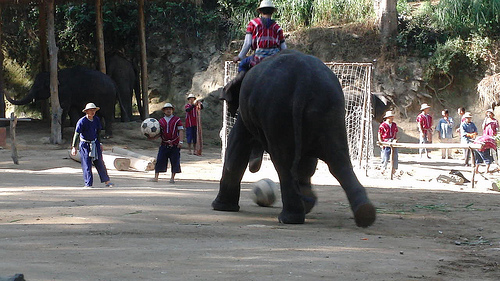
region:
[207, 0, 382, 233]
a man riding an elephant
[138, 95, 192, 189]
a man holding a large soccer ball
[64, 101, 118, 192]
a man wearing blue and brimmed hat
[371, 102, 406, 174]
a man wearing a red shirt and a hat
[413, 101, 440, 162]
a man wearing a red shirt and a hat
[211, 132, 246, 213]
a front leg of an elephant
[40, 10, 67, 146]
the trunk of a tree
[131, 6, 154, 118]
the trunk of a tree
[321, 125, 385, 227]
the hind leg of an elephant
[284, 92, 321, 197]
the tail of an elephant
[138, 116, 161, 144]
a man holds a large soccer ball.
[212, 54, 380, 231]
an elephant plays soccer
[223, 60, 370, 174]
a white goal net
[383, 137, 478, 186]
A table made from logs and planks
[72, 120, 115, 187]
man wears a grey shirt under a blue uniform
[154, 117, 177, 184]
most men wear red tope with white trim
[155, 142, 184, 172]
short pants with full cut legs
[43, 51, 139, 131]
other elephants wait between the trees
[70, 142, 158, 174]
heavy logs lay on the ground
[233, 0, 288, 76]
man rides an elephant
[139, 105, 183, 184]
man holding large soccer ball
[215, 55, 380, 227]
elephant rolling large soccer ball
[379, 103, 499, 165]
group of people standing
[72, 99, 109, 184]
man in blue shirt and pants with white hat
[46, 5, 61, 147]
straight brown tree trunk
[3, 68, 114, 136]
dark elephant behind tree trunk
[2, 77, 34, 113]
trunk of elephant is curved upward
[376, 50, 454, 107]
roots of large tree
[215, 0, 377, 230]
man riding dark colored elephant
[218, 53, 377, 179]
white net on soccer goal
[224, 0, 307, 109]
man riding an elephant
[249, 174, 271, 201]
over sized soccer ball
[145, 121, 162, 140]
over sized soccer ball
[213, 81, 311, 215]
elephant kicking a soccer ball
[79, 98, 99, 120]
man wearing a sun hat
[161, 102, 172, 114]
man wearing a sun hat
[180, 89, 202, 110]
man wearing a sun hat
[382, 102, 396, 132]
man wearing a sun hat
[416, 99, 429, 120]
man wearing a sun hat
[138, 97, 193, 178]
man holding giant soccer ball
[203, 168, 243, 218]
the foot of an elephant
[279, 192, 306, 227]
the foot of an elephant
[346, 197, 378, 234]
the foot of an elephant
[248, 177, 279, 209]
a large soccer ball rolling on the ground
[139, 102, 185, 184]
a man holding a ball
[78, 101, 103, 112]
a man in a large hat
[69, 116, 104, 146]
a man in a blue shirt